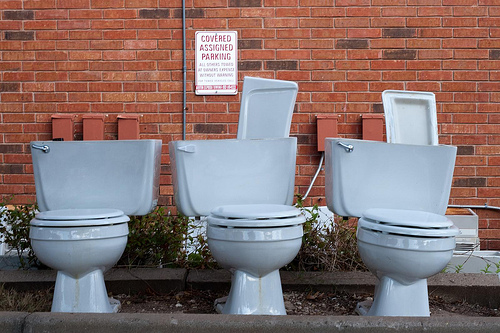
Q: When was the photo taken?
A: Daytime.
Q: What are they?
A: Toilets.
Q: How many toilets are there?
A: 3.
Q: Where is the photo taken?
A: Outside the house.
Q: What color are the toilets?
A: White.